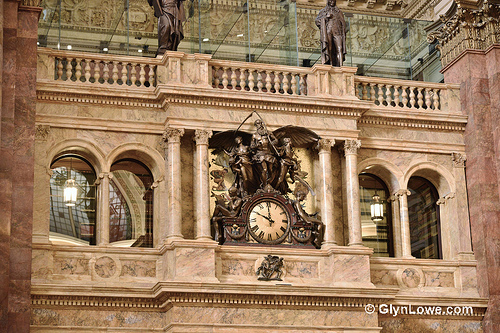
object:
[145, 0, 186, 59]
statue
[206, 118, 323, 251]
clock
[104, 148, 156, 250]
window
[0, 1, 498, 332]
building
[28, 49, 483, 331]
wall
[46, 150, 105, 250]
arch way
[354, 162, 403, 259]
window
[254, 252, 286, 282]
emblem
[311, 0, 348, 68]
statue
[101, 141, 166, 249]
ancient